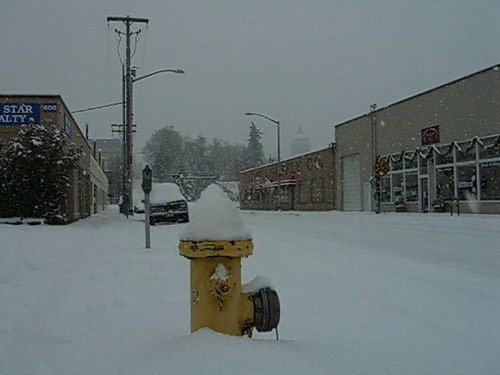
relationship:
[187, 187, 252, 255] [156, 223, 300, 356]
snow on hydrant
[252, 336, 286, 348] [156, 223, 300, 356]
chain on hydrant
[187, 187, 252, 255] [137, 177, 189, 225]
snow on truck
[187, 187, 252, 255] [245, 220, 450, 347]
snow in street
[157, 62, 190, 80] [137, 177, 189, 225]
lamp over truck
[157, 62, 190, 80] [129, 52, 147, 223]
lamp on pole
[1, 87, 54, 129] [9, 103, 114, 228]
sign on building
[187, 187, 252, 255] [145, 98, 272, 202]
snow on trees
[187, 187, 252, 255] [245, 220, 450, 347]
snow on street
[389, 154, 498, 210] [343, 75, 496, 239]
windows on building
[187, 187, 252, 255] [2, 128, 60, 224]
snow on tree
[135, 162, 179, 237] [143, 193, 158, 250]
meter on pole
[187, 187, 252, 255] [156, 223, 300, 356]
snow piled on hydrant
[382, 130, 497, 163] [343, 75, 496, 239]
garland on building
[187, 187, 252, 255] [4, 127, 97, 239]
snow on bush